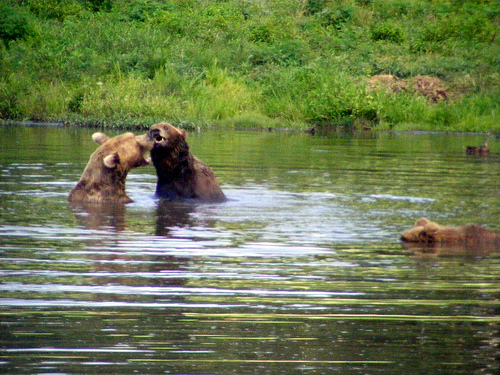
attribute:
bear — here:
[397, 213, 496, 255]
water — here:
[4, 118, 496, 370]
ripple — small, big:
[127, 284, 362, 301]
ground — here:
[15, 76, 490, 121]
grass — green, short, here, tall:
[44, 62, 343, 110]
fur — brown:
[177, 163, 225, 186]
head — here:
[89, 126, 156, 171]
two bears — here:
[64, 115, 230, 223]